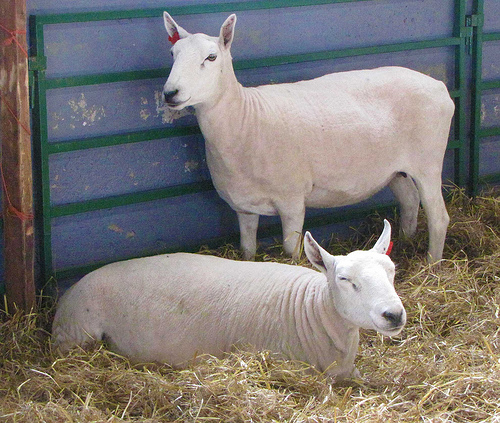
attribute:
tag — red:
[169, 33, 188, 46]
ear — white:
[155, 3, 195, 49]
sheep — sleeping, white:
[51, 237, 430, 377]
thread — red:
[4, 102, 38, 139]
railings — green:
[46, 18, 132, 121]